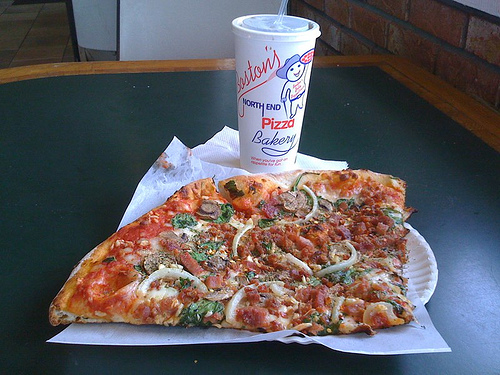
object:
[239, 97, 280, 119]
north end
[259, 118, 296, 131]
word pizza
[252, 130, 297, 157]
bakery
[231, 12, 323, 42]
lid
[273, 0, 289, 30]
straw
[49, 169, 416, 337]
slices of  pizza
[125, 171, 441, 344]
plate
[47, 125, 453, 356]
paper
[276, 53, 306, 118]
figure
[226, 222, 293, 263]
onions and sausage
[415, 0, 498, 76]
wall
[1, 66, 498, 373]
table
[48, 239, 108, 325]
crust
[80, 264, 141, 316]
tomato sauce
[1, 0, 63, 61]
floor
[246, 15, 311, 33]
soda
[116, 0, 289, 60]
object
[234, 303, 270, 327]
toppings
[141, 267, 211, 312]
onions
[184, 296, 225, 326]
basil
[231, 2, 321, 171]
cup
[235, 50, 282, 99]
boston